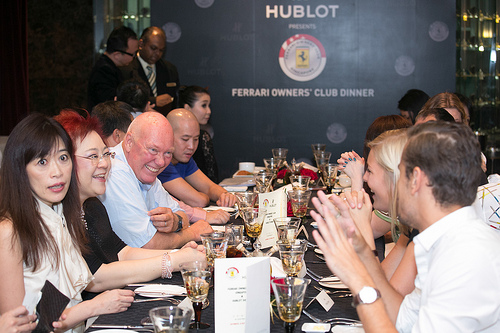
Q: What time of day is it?
A: Daytime.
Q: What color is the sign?
A: Black.